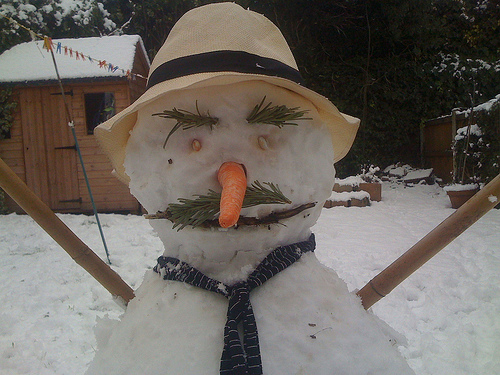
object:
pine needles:
[252, 95, 267, 121]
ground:
[0, 207, 500, 375]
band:
[143, 48, 305, 91]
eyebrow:
[246, 93, 315, 130]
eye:
[189, 138, 203, 153]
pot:
[443, 184, 481, 210]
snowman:
[85, 2, 416, 375]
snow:
[74, 77, 420, 375]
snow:
[0, 34, 139, 81]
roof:
[0, 35, 141, 84]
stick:
[0, 158, 134, 302]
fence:
[421, 100, 500, 199]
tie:
[146, 230, 317, 375]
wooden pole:
[359, 176, 500, 308]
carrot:
[217, 161, 249, 229]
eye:
[257, 134, 273, 152]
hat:
[92, 0, 362, 188]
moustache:
[143, 179, 292, 233]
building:
[0, 33, 160, 216]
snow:
[0, 207, 500, 375]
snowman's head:
[90, 0, 363, 260]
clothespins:
[56, 41, 62, 54]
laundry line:
[0, 11, 146, 82]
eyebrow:
[151, 98, 220, 150]